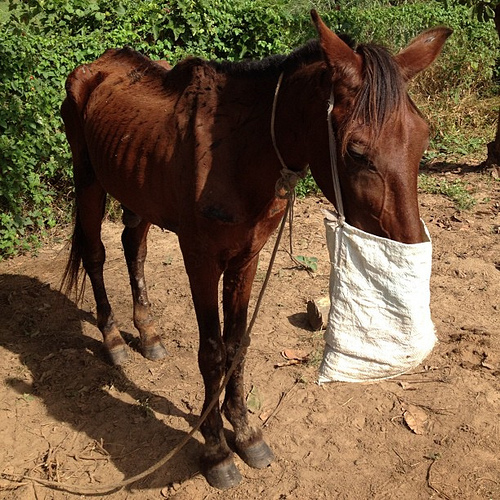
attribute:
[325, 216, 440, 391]
feedbag — white, over snout, tied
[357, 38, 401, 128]
hair — brown, black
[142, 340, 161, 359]
hoof — black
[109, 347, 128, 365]
hoof — black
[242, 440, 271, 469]
hoof — black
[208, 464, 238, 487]
hoof — black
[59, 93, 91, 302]
tail — brown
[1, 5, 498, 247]
leaf — green, behind horse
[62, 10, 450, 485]
horse — brown, eating, small, feeding, poor, malnourished, thin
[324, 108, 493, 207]
grass — green, in the dirt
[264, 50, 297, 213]
rope — lead, tie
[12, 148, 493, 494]
soil — dusty, brown, dry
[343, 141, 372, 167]
eyes — downtrodden, ill